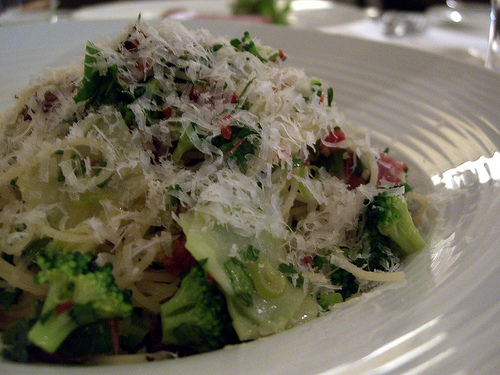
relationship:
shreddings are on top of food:
[7, 12, 343, 184] [1, 14, 430, 367]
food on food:
[1, 14, 430, 367] [1, 14, 429, 368]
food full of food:
[1, 14, 429, 368] [1, 14, 430, 367]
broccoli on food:
[24, 256, 130, 355] [1, 14, 429, 368]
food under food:
[1, 14, 429, 368] [1, 14, 430, 367]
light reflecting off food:
[428, 150, 499, 203] [1, 14, 429, 368]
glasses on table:
[360, 2, 499, 73] [0, 0, 500, 71]